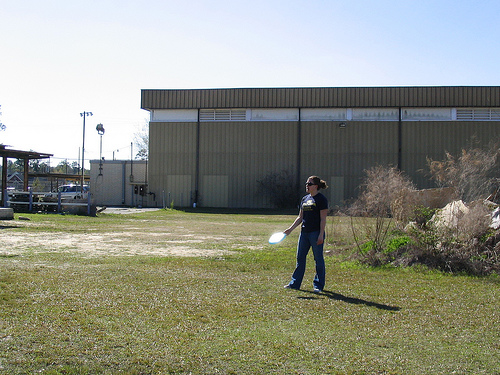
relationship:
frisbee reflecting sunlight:
[267, 230, 285, 244] [267, 230, 284, 243]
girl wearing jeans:
[280, 174, 331, 296] [288, 228, 329, 288]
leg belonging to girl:
[289, 242, 310, 287] [280, 174, 331, 296]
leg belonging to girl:
[309, 236, 325, 287] [280, 174, 331, 296]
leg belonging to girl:
[289, 233, 311, 287] [280, 174, 331, 296]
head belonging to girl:
[303, 172, 322, 195] [280, 174, 331, 296]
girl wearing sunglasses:
[280, 174, 331, 296] [304, 180, 315, 186]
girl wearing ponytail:
[280, 174, 331, 296] [320, 179, 329, 191]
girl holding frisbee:
[280, 174, 331, 296] [266, 230, 286, 245]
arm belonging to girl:
[287, 203, 303, 233] [280, 174, 331, 296]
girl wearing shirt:
[280, 174, 331, 296] [298, 191, 330, 233]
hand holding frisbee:
[282, 228, 292, 236] [267, 230, 284, 245]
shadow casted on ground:
[297, 283, 401, 314] [3, 206, 499, 373]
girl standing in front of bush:
[280, 174, 331, 296] [342, 161, 420, 262]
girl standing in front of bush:
[280, 174, 331, 296] [413, 203, 456, 263]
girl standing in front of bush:
[280, 174, 331, 296] [414, 132, 484, 199]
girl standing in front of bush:
[280, 174, 331, 296] [454, 198, 484, 246]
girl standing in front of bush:
[280, 174, 331, 296] [325, 201, 357, 247]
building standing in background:
[140, 85, 499, 212] [0, 82, 484, 233]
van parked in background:
[41, 180, 90, 201] [0, 82, 484, 233]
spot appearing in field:
[1, 228, 250, 260] [2, 203, 499, 373]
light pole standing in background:
[76, 109, 94, 199] [0, 82, 484, 233]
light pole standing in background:
[94, 122, 104, 158] [0, 82, 484, 233]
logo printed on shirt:
[301, 199, 315, 207] [298, 191, 330, 233]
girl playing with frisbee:
[280, 174, 331, 296] [266, 230, 286, 245]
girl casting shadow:
[280, 174, 331, 296] [297, 283, 401, 314]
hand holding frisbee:
[282, 228, 292, 236] [268, 230, 285, 246]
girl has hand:
[280, 174, 331, 296] [284, 225, 289, 236]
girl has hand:
[280, 174, 331, 296] [316, 231, 325, 247]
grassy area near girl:
[0, 210, 499, 373] [280, 174, 331, 296]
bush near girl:
[380, 229, 413, 253] [280, 174, 331, 296]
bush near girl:
[324, 142, 499, 278] [280, 174, 331, 296]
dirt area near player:
[3, 220, 275, 260] [282, 166, 331, 294]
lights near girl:
[75, 106, 95, 118] [280, 174, 331, 296]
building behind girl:
[138, 81, 498, 215] [280, 174, 331, 296]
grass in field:
[2, 205, 498, 373] [2, 203, 499, 373]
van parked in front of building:
[41, 183, 90, 200] [86, 156, 152, 209]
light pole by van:
[80, 112, 87, 200] [41, 183, 90, 200]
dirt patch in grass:
[2, 220, 280, 264] [2, 205, 498, 373]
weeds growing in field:
[329, 140, 497, 280] [2, 203, 499, 373]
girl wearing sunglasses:
[284, 172, 330, 302] [304, 183, 317, 188]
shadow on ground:
[297, 283, 401, 314] [3, 206, 499, 373]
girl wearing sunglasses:
[280, 174, 331, 296] [303, 176, 320, 187]